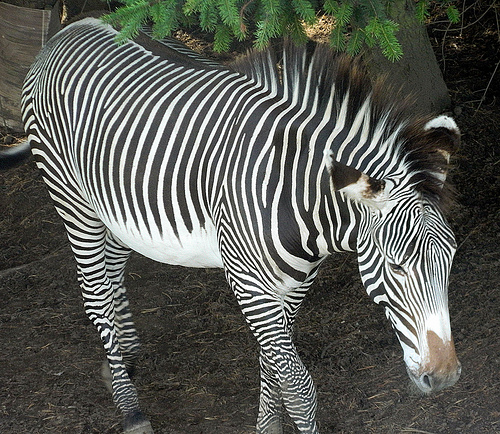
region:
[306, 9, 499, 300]
A zebra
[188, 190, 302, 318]
A zebra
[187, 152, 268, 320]
A zebra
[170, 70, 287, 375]
A zebra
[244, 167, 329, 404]
A zebra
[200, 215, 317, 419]
A zebra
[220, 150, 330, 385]
A zebra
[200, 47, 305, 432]
A zebra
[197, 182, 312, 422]
A zebra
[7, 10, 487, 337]
the zebra has stripes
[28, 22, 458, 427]
black and white striped zebra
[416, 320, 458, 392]
brown nose of black and white striped zebra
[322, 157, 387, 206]
right ear of black and white striped zebra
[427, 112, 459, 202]
left ear of black and white striped zebra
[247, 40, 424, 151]
mane of black and white striped zebra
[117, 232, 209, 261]
white stomach of zebra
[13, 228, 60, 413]
gray dirt and leaves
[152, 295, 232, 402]
gray dirt and leaves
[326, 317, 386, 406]
gray dirt and leaves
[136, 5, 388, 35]
green leaves of tree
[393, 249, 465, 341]
A zebra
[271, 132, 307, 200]
A zebra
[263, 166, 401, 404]
A zebra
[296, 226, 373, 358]
A zebra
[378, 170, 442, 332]
A zebra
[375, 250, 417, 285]
a zebra's left eye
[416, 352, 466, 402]
a nose of a zebra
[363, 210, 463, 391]
a head of a zebra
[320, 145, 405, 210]
an ear of a zebra curled down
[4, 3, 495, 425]
a zebra eating grass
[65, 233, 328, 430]
legs of a zebra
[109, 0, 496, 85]
green trees in background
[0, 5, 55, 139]
wooden post next to zebra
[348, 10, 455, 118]
a trunk of a tree behind zebra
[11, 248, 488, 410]
grassy area zebra is grazing